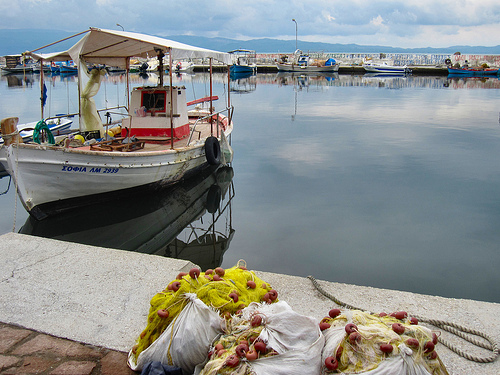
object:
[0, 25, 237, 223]
boat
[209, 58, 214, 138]
pole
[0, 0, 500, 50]
clouds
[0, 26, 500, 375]
scene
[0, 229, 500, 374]
harbor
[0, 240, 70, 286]
crack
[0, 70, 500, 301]
water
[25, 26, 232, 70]
roof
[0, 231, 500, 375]
pavement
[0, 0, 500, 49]
sky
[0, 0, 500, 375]
background